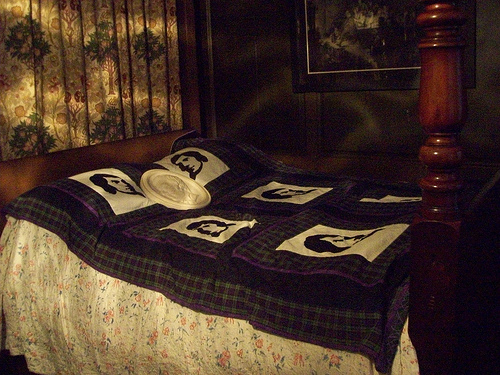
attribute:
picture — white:
[68, 168, 153, 212]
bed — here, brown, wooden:
[1, 130, 422, 374]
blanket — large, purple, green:
[16, 129, 415, 374]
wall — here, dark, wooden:
[195, 1, 291, 143]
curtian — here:
[1, 1, 184, 164]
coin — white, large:
[139, 164, 211, 210]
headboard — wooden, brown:
[410, 166, 498, 373]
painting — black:
[286, 1, 418, 93]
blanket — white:
[1, 237, 87, 373]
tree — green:
[84, 19, 125, 98]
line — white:
[303, 1, 313, 77]